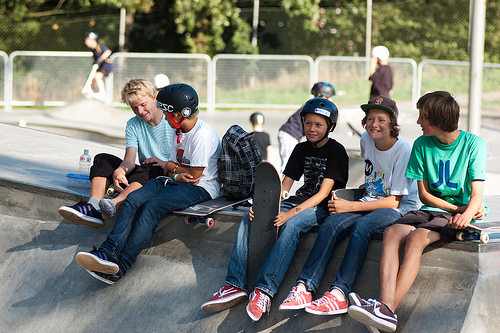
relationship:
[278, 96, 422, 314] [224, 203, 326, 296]
boy wearing jeans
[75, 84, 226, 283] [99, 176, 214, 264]
boy wearing jeans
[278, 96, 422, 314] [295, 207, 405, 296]
boy wearing jeans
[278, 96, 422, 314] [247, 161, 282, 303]
boy holding skateboard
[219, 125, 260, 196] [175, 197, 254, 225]
book bag on skateboard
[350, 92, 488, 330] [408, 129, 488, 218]
boy wearing shirt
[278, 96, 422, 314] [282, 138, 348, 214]
boy wearing shirt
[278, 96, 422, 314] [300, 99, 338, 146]
boy wearing helmet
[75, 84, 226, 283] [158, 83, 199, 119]
boy wearing helmet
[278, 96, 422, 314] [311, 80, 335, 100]
boy wearing helmet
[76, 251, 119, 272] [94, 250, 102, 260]
tinnis shoe has stripe